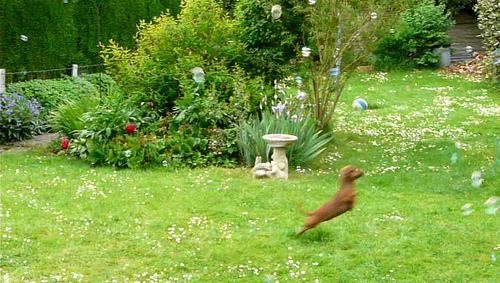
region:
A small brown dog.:
[299, 149, 371, 253]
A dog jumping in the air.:
[294, 154, 379, 246]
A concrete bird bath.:
[243, 126, 299, 179]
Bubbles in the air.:
[441, 145, 499, 232]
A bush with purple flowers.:
[2, 83, 43, 148]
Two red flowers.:
[54, 109, 154, 169]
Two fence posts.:
[0, 57, 96, 87]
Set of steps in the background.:
[433, 9, 488, 68]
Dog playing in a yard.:
[45, 16, 482, 275]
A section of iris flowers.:
[229, 85, 341, 175]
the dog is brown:
[290, 160, 375, 237]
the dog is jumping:
[293, 155, 372, 242]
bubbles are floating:
[146, 11, 498, 253]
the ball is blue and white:
[343, 95, 379, 117]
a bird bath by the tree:
[248, 126, 301, 181]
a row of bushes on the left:
[3, 70, 125, 147]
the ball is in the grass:
[346, 91, 371, 116]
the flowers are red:
[58, 118, 138, 155]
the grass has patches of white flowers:
[19, 75, 496, 280]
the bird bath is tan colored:
[244, 127, 301, 180]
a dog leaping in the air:
[291, 163, 368, 238]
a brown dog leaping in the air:
[292, 167, 364, 238]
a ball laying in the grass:
[352, 97, 367, 112]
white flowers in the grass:
[212, 246, 327, 281]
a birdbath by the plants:
[251, 132, 296, 181]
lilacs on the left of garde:
[2, 92, 45, 143]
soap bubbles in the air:
[457, 172, 497, 217]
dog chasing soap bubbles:
[295, 164, 367, 236]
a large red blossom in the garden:
[122, 121, 137, 136]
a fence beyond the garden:
[2, 58, 111, 99]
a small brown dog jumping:
[293, 162, 365, 239]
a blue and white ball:
[351, 97, 368, 109]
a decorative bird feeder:
[250, 132, 296, 177]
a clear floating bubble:
[460, 200, 475, 215]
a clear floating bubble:
[485, 195, 497, 212]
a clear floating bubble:
[485, 241, 495, 256]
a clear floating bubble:
[469, 168, 484, 188]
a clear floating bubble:
[189, 65, 207, 82]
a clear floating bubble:
[269, 1, 281, 19]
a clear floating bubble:
[301, 47, 310, 56]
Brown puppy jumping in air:
[296, 160, 367, 245]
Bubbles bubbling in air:
[461, 152, 498, 223]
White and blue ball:
[353, 95, 368, 112]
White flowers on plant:
[260, 88, 310, 127]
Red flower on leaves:
[119, 120, 138, 132]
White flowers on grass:
[0, 152, 336, 282]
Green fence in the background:
[0, 1, 165, 68]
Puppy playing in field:
[295, 165, 368, 242]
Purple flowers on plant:
[0, 89, 46, 129]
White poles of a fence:
[0, 57, 85, 91]